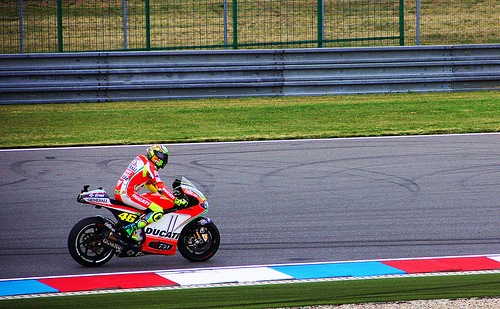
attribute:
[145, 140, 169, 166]
helmet — red, green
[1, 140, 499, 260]
tire marks — burnout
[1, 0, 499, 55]
fence — metallic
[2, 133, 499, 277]
track — asphalt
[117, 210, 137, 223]
number — bright yellow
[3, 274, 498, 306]
infield — grassy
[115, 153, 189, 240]
clothing — special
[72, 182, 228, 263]
motorcycle — red, white, black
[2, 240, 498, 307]
raceway side — blue, red, white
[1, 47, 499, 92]
guardrail — dark gray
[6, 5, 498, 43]
fence — wire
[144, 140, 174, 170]
helmet — multi-color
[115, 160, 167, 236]
outfit — red, white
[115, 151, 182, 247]
suit — red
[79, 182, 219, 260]
motorcycle — red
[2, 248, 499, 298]
line — striped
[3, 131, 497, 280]
racetrack — asphalt, paved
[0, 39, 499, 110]
wall — metal